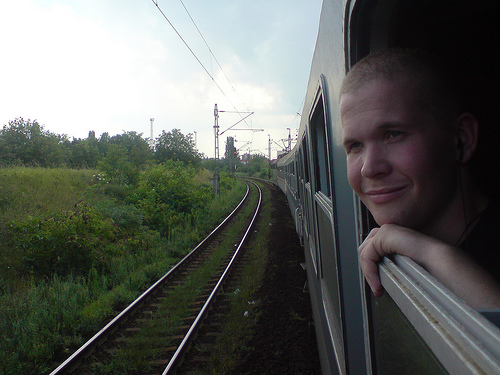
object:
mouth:
[358, 185, 410, 202]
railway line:
[50, 178, 261, 373]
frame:
[347, 0, 499, 329]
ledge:
[358, 212, 498, 372]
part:
[213, 124, 220, 139]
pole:
[213, 105, 219, 167]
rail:
[157, 285, 212, 295]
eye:
[382, 127, 407, 142]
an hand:
[326, 205, 434, 290]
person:
[315, 58, 490, 315]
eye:
[345, 137, 367, 154]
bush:
[96, 146, 152, 209]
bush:
[4, 122, 68, 164]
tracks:
[39, 178, 269, 373]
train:
[275, 2, 497, 374]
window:
[301, 103, 344, 200]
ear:
[448, 113, 489, 165]